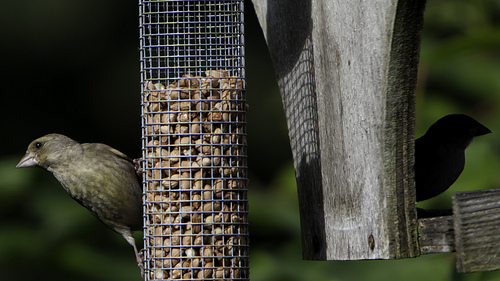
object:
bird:
[15, 131, 145, 275]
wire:
[137, 1, 252, 279]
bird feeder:
[137, 1, 249, 279]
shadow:
[408, 109, 492, 204]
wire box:
[136, 0, 249, 279]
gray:
[253, 2, 421, 260]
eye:
[32, 140, 45, 152]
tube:
[136, 1, 249, 280]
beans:
[141, 68, 246, 280]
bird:
[412, 113, 490, 203]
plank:
[249, 2, 430, 262]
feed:
[142, 69, 246, 280]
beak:
[15, 151, 36, 168]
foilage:
[1, 3, 498, 279]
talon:
[135, 251, 148, 276]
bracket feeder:
[416, 184, 497, 271]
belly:
[87, 167, 127, 209]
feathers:
[92, 170, 121, 203]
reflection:
[242, 3, 329, 261]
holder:
[418, 209, 456, 254]